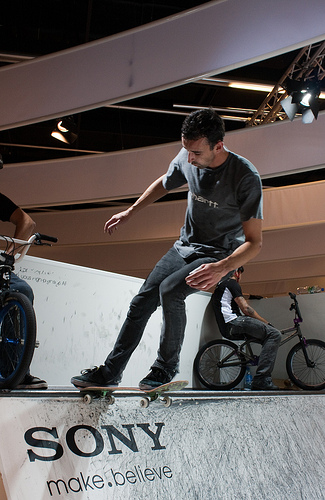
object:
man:
[68, 109, 265, 390]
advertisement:
[23, 421, 172, 498]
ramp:
[0, 388, 325, 499]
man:
[0, 157, 47, 389]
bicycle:
[0, 229, 58, 395]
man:
[209, 265, 284, 391]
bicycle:
[192, 293, 324, 392]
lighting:
[278, 81, 304, 124]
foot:
[136, 368, 176, 390]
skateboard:
[75, 376, 188, 409]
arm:
[232, 287, 266, 326]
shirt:
[161, 143, 262, 266]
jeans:
[100, 248, 226, 379]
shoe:
[138, 366, 166, 394]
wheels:
[81, 391, 92, 406]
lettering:
[211, 201, 218, 209]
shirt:
[214, 276, 242, 330]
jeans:
[220, 315, 282, 383]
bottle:
[295, 284, 324, 294]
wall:
[237, 291, 323, 389]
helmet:
[224, 264, 243, 277]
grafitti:
[15, 266, 69, 289]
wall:
[0, 249, 241, 387]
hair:
[179, 110, 224, 150]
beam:
[0, 1, 324, 130]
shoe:
[251, 374, 281, 390]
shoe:
[17, 371, 49, 393]